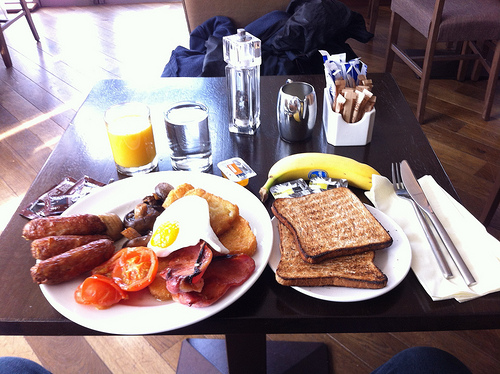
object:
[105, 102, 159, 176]
glass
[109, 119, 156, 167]
orange juice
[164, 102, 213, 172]
glass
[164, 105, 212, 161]
water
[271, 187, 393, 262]
toast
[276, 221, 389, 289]
toast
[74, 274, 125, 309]
tomato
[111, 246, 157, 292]
tomato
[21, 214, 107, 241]
sausage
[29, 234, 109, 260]
sausage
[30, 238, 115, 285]
sausage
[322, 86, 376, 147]
container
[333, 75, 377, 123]
sugar packets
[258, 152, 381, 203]
banana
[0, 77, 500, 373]
table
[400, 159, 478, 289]
knife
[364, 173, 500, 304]
napkin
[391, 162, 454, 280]
fork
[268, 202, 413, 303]
plate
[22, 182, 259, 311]
foods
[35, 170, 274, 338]
plate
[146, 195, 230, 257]
egg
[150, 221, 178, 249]
yolk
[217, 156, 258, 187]
container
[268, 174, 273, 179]
spot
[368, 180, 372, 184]
spot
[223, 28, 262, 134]
grinder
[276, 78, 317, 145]
pitcher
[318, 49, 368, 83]
sweetener packets